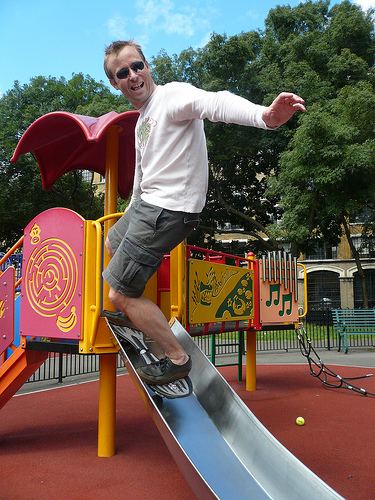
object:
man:
[103, 34, 306, 395]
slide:
[32, 300, 95, 359]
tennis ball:
[294, 412, 304, 425]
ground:
[212, 356, 372, 500]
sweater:
[106, 82, 268, 212]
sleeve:
[196, 84, 265, 141]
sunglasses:
[115, 59, 145, 78]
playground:
[0, 96, 375, 484]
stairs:
[0, 338, 50, 408]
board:
[254, 252, 309, 329]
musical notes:
[262, 281, 299, 322]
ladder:
[295, 317, 375, 400]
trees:
[0, 4, 375, 316]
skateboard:
[105, 312, 201, 401]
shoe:
[137, 355, 192, 384]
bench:
[328, 291, 369, 354]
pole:
[91, 355, 121, 471]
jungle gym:
[14, 198, 311, 437]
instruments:
[255, 243, 304, 293]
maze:
[22, 218, 85, 341]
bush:
[9, 80, 95, 204]